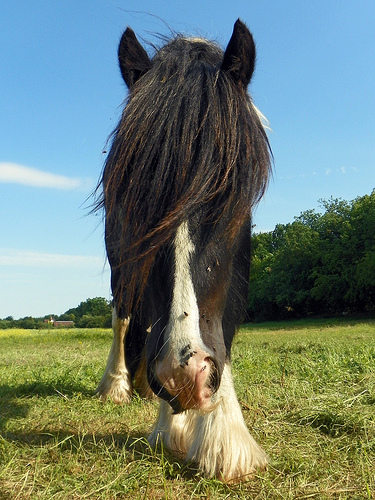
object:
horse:
[94, 17, 274, 484]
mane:
[83, 32, 276, 318]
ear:
[117, 26, 152, 90]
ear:
[221, 18, 256, 87]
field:
[0, 317, 375, 499]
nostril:
[210, 365, 221, 392]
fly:
[184, 312, 188, 317]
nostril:
[164, 369, 175, 392]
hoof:
[154, 395, 267, 486]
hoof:
[95, 354, 133, 404]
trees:
[247, 191, 375, 320]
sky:
[1, 4, 375, 321]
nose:
[153, 348, 221, 414]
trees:
[75, 297, 112, 328]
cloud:
[0, 162, 82, 189]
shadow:
[1, 382, 150, 449]